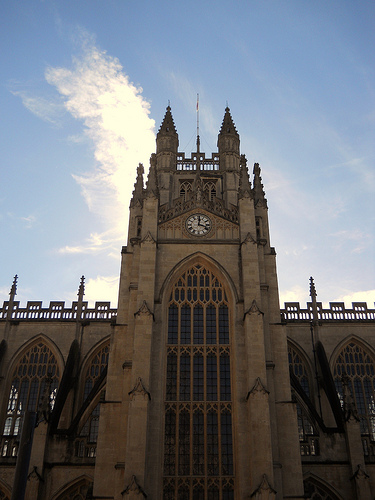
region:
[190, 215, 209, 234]
White clock on side of building.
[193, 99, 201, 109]
Flag at the top of a building.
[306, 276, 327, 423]
Building spire on side of building.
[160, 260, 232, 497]
Cathedral window in front of building.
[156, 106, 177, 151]
Steeple spire on top of building.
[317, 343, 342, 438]
Large flag in front of building.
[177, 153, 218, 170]
Stone railing on top of building.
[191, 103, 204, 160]
State flag on top of building.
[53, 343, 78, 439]
Building identifying flag hanging.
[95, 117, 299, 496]
Cathedral style building in city.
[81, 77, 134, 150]
The cloud is white.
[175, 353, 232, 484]
The windows are long.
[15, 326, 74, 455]
The window is arched.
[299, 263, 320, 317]
Cross on a pole.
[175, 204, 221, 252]
Clock on the building.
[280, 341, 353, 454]
A black railing on the building.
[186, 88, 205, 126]
Red flag on a pole.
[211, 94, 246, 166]
A tower on the building.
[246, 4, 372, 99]
The sky is blue.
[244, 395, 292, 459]
The building is brown.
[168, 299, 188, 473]
long brown lines in front of buildings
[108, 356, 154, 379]
large square spot on column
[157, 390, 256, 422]
decorative design on building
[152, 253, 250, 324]
triangular design on the building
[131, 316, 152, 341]
two tone brown colors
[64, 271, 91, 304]
tall spiral on top of building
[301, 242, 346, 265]
stormy clouds in the sky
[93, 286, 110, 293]
clear white skies overhead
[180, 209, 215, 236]
large white circular clock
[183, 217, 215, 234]
roman numerals in the clock's face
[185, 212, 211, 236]
a round clock face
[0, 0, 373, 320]
a blue sky over a building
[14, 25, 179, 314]
white clouds in the sky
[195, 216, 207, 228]
the black hands of a clock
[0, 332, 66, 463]
a large segmented window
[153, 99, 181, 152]
the spire on a building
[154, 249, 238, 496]
the central segmented window of a building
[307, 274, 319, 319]
a pole on a building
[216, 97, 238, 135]
the tip of a spire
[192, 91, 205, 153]
the tallest pole on a building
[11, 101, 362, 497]
photograph of old church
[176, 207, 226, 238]
clock with white face on church tower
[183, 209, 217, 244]
clock with black roman numerals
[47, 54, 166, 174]
white clouds in clear sky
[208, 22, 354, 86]
bright blue clear sky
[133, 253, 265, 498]
glass windows on church tower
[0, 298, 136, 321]
fencing on top of building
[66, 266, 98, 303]
decorative cross structure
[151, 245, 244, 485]
light brown window panes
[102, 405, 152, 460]
building made of brown brick